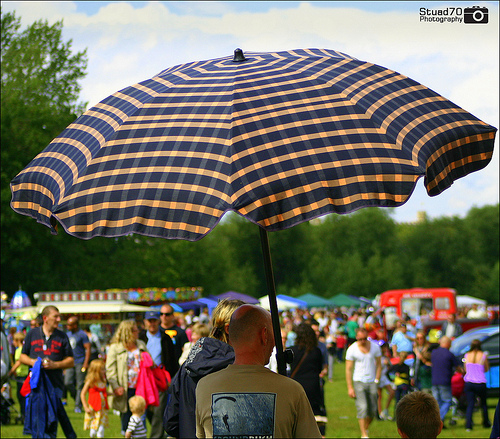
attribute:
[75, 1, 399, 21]
sky — blue 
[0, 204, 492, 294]
forest — green 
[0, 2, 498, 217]
cloudy sky — blue 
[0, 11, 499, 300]
trees — tall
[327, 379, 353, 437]
grass — green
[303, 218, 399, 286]
leaves — green 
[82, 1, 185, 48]
clouds — white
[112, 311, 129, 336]
hair — blonde 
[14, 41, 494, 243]
umbrella — yellow, black, plaid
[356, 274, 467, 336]
bus — red 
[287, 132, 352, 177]
dots — orange 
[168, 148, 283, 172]
dots — orange 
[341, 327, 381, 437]
person — blurry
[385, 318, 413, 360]
person — blurry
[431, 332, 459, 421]
person — blurry